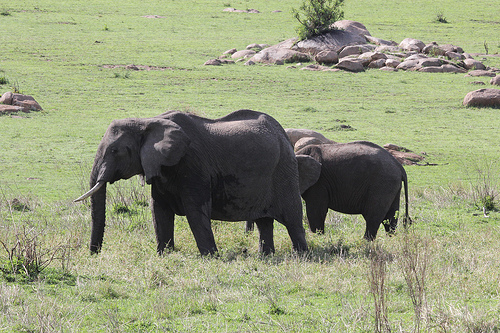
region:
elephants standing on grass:
[97, 87, 417, 262]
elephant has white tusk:
[68, 170, 146, 221]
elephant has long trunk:
[63, 132, 111, 279]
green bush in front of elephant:
[1, 184, 86, 285]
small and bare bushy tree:
[340, 231, 423, 328]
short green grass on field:
[1, 13, 496, 184]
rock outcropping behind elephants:
[227, 14, 498, 131]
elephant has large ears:
[129, 129, 186, 180]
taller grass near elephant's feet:
[108, 246, 396, 294]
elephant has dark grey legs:
[145, 191, 236, 276]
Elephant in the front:
[83, 103, 313, 262]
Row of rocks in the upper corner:
[202, 18, 492, 73]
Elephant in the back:
[283, 125, 413, 242]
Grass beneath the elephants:
[0, 247, 499, 329]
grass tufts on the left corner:
[7, 206, 75, 298]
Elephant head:
[79, 113, 181, 260]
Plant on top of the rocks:
[290, 0, 359, 62]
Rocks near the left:
[0, 71, 45, 140]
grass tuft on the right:
[450, 136, 499, 211]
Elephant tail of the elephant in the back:
[351, 142, 426, 254]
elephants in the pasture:
[70, 98, 444, 287]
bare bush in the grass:
[11, 215, 66, 271]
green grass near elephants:
[266, 74, 378, 100]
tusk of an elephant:
[74, 181, 103, 209]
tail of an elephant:
[396, 164, 419, 234]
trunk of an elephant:
[84, 196, 109, 262]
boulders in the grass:
[327, 21, 478, 84]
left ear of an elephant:
[141, 114, 187, 182]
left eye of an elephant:
[106, 138, 133, 163]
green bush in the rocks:
[285, 1, 353, 47]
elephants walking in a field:
[79, 103, 411, 264]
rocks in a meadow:
[200, 0, 497, 113]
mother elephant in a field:
[75, 105, 315, 263]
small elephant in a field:
[284, 124, 414, 243]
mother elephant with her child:
[73, 104, 423, 253]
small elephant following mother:
[70, 100, 438, 258]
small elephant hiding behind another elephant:
[75, 103, 413, 259]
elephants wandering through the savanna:
[72, 104, 419, 261]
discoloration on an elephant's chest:
[147, 150, 247, 225]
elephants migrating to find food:
[71, 103, 413, 251]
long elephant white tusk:
[74, 174, 119, 215]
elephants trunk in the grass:
[82, 200, 109, 267]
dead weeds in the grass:
[344, 244, 439, 321]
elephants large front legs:
[152, 197, 219, 258]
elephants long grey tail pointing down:
[394, 165, 410, 240]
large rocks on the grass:
[366, 41, 471, 83]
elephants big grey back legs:
[256, 197, 308, 260]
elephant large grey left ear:
[139, 116, 183, 192]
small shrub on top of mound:
[298, 1, 351, 51]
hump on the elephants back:
[166, 108, 203, 133]